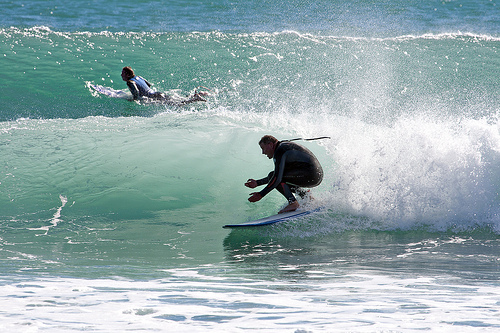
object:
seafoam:
[26, 193, 68, 238]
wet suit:
[254, 141, 324, 203]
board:
[91, 85, 134, 101]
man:
[120, 66, 209, 105]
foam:
[0, 258, 497, 333]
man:
[245, 135, 324, 215]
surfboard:
[222, 208, 316, 228]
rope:
[281, 137, 331, 143]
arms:
[260, 154, 286, 196]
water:
[0, 0, 500, 333]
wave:
[0, 25, 500, 224]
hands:
[247, 192, 263, 203]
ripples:
[0, 216, 499, 324]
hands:
[245, 179, 259, 189]